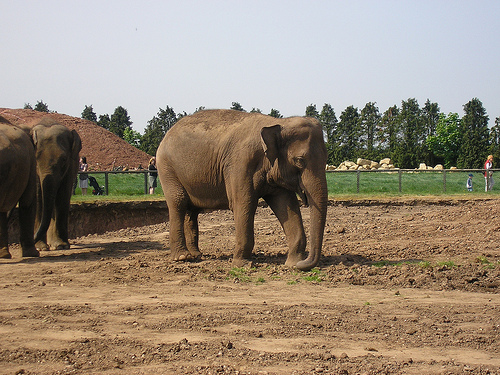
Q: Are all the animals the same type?
A: Yes, all the animals are elephants.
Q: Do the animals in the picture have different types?
A: No, all the animals are elephants.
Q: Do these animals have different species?
A: No, all the animals are elephants.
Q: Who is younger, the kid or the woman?
A: The kid is younger than the woman.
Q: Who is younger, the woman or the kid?
A: The kid is younger than the woman.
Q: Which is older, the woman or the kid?
A: The woman is older than the kid.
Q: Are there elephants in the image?
A: Yes, there is an elephant.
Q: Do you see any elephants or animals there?
A: Yes, there is an elephant.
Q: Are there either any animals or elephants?
A: Yes, there is an elephant.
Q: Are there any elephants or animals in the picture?
A: Yes, there is an elephant.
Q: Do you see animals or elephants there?
A: Yes, there is an elephant.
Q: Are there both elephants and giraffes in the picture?
A: No, there is an elephant but no giraffes.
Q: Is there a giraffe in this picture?
A: No, there are no giraffes.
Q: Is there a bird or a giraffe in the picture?
A: No, there are no giraffes or birds.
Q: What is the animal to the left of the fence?
A: The animal is an elephant.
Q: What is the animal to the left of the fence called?
A: The animal is an elephant.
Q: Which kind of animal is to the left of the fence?
A: The animal is an elephant.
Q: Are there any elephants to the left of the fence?
A: Yes, there is an elephant to the left of the fence.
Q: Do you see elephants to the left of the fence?
A: Yes, there is an elephant to the left of the fence.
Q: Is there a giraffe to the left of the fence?
A: No, there is an elephant to the left of the fence.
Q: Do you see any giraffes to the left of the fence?
A: No, there is an elephant to the left of the fence.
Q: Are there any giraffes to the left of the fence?
A: No, there is an elephant to the left of the fence.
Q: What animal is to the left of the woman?
A: The animal is an elephant.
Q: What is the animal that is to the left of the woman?
A: The animal is an elephant.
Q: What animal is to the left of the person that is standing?
A: The animal is an elephant.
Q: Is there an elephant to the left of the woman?
A: Yes, there is an elephant to the left of the woman.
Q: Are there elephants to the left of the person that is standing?
A: Yes, there is an elephant to the left of the woman.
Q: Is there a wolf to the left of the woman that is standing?
A: No, there is an elephant to the left of the woman.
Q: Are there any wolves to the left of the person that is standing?
A: No, there is an elephant to the left of the woman.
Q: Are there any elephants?
A: Yes, there is an elephant.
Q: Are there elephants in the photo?
A: Yes, there is an elephant.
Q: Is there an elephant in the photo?
A: Yes, there is an elephant.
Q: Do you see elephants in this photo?
A: Yes, there is an elephant.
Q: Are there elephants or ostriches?
A: Yes, there is an elephant.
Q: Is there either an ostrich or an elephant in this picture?
A: Yes, there is an elephant.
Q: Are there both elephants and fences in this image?
A: Yes, there are both an elephant and a fence.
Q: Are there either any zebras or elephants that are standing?
A: Yes, the elephant is standing.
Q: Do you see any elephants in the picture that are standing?
A: Yes, there is an elephant that is standing.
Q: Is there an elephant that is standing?
A: Yes, there is an elephant that is standing.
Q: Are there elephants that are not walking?
A: Yes, there is an elephant that is standing.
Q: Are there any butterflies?
A: No, there are no butterflies.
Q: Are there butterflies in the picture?
A: No, there are no butterflies.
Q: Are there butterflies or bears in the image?
A: No, there are no butterflies or bears.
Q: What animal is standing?
A: The animal is an elephant.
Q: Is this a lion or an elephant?
A: This is an elephant.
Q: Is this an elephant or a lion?
A: This is an elephant.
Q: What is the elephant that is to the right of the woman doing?
A: The elephant is standing.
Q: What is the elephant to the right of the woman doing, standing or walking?
A: The elephant is standing.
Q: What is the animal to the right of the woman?
A: The animal is an elephant.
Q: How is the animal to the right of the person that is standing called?
A: The animal is an elephant.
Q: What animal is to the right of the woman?
A: The animal is an elephant.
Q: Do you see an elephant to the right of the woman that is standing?
A: Yes, there is an elephant to the right of the woman.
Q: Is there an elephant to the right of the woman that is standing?
A: Yes, there is an elephant to the right of the woman.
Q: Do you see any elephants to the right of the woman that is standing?
A: Yes, there is an elephant to the right of the woman.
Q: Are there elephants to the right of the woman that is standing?
A: Yes, there is an elephant to the right of the woman.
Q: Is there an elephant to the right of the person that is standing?
A: Yes, there is an elephant to the right of the woman.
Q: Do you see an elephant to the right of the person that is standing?
A: Yes, there is an elephant to the right of the woman.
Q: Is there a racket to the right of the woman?
A: No, there is an elephant to the right of the woman.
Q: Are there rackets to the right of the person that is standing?
A: No, there is an elephant to the right of the woman.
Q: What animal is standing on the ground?
A: The elephant is standing on the ground.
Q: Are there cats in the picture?
A: No, there are no cats.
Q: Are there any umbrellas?
A: No, there are no umbrellas.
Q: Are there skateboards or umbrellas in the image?
A: No, there are no umbrellas or skateboards.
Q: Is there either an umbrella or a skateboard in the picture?
A: No, there are no umbrellas or skateboards.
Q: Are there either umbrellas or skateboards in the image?
A: No, there are no umbrellas or skateboards.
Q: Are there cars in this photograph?
A: No, there are no cars.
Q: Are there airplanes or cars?
A: No, there are no cars or airplanes.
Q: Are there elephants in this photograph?
A: Yes, there is an elephant.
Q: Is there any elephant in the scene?
A: Yes, there is an elephant.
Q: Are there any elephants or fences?
A: Yes, there is an elephant.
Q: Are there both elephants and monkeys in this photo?
A: No, there is an elephant but no monkeys.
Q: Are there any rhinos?
A: No, there are no rhinos.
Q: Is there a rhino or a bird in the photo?
A: No, there are no rhinos or birds.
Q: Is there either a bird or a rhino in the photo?
A: No, there are no rhinos or birds.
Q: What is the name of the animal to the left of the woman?
A: The animal is an elephant.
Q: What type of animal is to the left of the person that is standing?
A: The animal is an elephant.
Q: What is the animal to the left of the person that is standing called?
A: The animal is an elephant.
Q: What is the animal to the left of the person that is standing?
A: The animal is an elephant.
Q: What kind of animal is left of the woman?
A: The animal is an elephant.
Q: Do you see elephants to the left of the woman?
A: Yes, there is an elephant to the left of the woman.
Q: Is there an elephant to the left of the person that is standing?
A: Yes, there is an elephant to the left of the woman.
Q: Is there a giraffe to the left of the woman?
A: No, there is an elephant to the left of the woman.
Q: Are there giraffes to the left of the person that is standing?
A: No, there is an elephant to the left of the woman.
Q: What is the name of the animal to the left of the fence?
A: The animal is an elephant.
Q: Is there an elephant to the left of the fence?
A: Yes, there is an elephant to the left of the fence.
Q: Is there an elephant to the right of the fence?
A: No, the elephant is to the left of the fence.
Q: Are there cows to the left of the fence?
A: No, there is an elephant to the left of the fence.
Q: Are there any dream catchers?
A: No, there are no dream catchers.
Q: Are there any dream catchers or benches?
A: No, there are no dream catchers or benches.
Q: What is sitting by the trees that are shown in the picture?
A: The rocks are sitting by the trees.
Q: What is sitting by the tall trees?
A: The rocks are sitting by the trees.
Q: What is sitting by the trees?
A: The rocks are sitting by the trees.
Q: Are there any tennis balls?
A: No, there are no tennis balls.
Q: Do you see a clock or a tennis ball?
A: No, there are no tennis balls or clocks.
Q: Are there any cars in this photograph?
A: No, there are no cars.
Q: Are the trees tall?
A: Yes, the trees are tall.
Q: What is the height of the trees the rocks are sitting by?
A: The trees are tall.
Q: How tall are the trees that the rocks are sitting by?
A: The trees are tall.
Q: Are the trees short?
A: No, the trees are tall.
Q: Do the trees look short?
A: No, the trees are tall.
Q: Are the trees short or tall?
A: The trees are tall.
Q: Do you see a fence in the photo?
A: Yes, there is a fence.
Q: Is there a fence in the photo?
A: Yes, there is a fence.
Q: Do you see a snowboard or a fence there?
A: Yes, there is a fence.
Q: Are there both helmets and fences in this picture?
A: No, there is a fence but no helmets.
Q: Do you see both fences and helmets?
A: No, there is a fence but no helmets.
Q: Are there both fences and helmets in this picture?
A: No, there is a fence but no helmets.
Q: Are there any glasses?
A: No, there are no glasses.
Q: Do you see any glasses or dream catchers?
A: No, there are no glasses or dream catchers.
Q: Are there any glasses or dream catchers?
A: No, there are no glasses or dream catchers.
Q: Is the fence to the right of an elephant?
A: Yes, the fence is to the right of an elephant.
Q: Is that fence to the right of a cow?
A: No, the fence is to the right of an elephant.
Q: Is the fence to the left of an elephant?
A: No, the fence is to the right of an elephant.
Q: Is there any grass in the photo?
A: Yes, there is grass.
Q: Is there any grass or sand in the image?
A: Yes, there is grass.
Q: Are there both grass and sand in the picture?
A: No, there is grass but no sand.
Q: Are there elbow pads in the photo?
A: No, there are no elbow pads.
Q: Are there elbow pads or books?
A: No, there are no elbow pads or books.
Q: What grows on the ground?
A: The grass grows on the ground.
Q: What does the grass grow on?
A: The grass grows on the ground.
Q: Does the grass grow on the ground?
A: Yes, the grass grows on the ground.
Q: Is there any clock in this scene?
A: No, there are no clocks.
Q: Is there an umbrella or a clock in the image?
A: No, there are no clocks or umbrellas.